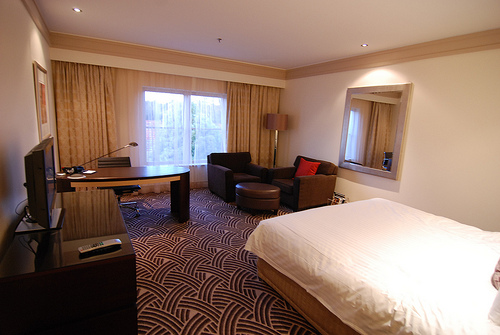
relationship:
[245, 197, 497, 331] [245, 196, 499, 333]
sheet on bed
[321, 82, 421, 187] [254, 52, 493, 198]
mirror on wall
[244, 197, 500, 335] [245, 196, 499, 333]
bed on bed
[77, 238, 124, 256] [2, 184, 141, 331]
controller on desk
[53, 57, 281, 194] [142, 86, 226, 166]
curtains on window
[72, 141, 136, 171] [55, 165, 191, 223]
lamp on a brown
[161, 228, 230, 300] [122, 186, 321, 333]
design on carpet